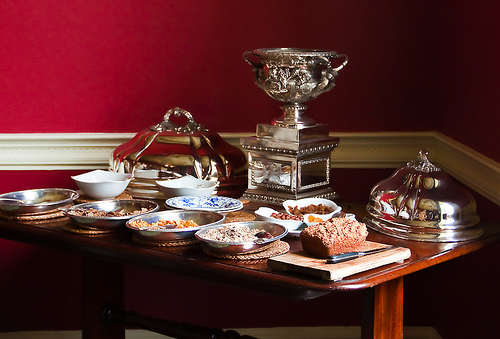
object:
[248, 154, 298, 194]
dot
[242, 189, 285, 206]
silver dot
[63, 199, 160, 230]
plate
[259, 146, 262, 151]
dot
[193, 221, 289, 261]
plate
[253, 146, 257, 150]
dot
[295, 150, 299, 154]
dot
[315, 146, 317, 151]
dot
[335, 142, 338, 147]
dot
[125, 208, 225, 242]
plate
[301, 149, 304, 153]
dot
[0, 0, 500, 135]
wall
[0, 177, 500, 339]
table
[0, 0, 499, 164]
wall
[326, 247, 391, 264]
knife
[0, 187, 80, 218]
plate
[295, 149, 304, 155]
dot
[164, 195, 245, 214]
red flowers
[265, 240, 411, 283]
board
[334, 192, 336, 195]
dot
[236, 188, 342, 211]
base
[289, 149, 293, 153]
dot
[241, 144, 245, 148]
dot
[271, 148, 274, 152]
dot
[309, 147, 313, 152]
dot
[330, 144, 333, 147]
dot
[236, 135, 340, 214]
base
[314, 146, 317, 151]
dot